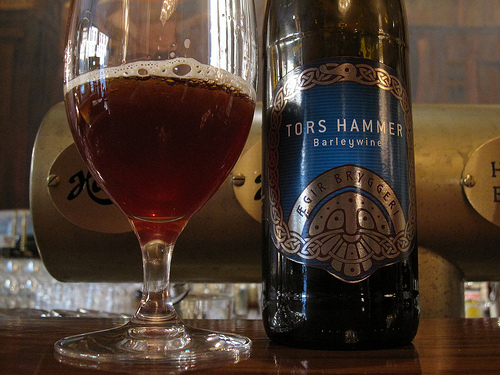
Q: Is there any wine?
A: Yes, there is wine.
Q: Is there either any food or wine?
A: Yes, there is wine.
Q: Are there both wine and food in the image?
A: No, there is wine but no food.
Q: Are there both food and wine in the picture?
A: No, there is wine but no food.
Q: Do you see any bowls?
A: No, there are no bowls.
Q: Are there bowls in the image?
A: No, there are no bowls.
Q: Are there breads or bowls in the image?
A: No, there are no bowls or breads.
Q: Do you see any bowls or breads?
A: No, there are no bowls or breads.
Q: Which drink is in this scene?
A: The drink is wine.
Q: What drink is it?
A: The drink is wine.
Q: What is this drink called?
A: This is wine.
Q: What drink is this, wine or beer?
A: This is wine.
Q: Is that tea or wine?
A: That is wine.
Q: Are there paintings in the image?
A: No, there are no paintings.